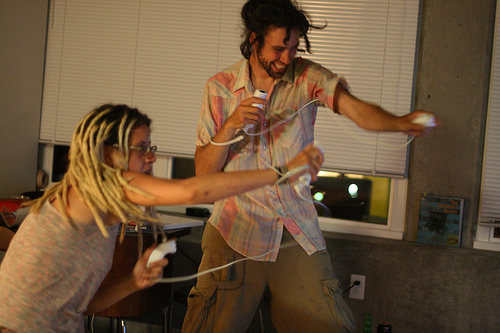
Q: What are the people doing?
A: Playing.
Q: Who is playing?
A: Two people.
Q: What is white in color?
A: Remotes.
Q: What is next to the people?
A: Window.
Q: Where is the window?
A: Next to the people.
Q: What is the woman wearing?
A: Gray top.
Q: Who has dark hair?
A: The young man.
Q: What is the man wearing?
A: Shirt.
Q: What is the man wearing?
A: Pant.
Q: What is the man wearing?
A: Shirt.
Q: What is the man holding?
A: Controller.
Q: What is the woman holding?
A: Controlelr.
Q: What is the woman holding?
A: Remote.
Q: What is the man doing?
A: Playign.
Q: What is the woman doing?
A: Playing.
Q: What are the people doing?
A: Playing.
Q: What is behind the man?
A: Wall.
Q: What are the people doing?
A: Playing game.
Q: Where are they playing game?
A: Living room.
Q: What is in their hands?
A: Controllers.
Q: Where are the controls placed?
A: Hands.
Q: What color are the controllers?
A: White.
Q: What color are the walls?
A: Brown.